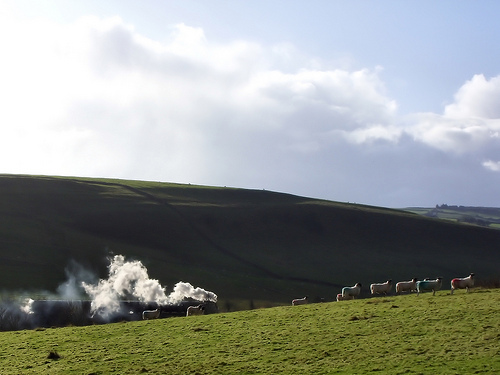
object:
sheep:
[394, 277, 417, 296]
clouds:
[405, 71, 496, 152]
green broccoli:
[408, 304, 414, 308]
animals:
[341, 281, 363, 299]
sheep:
[369, 279, 393, 295]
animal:
[415, 277, 443, 296]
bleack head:
[356, 281, 364, 288]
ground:
[296, 98, 382, 202]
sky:
[0, 1, 499, 179]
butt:
[451, 278, 460, 289]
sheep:
[448, 272, 478, 295]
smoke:
[70, 252, 222, 323]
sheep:
[450, 271, 473, 296]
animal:
[291, 296, 308, 306]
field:
[0, 285, 499, 375]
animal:
[140, 306, 161, 321]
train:
[2, 303, 214, 331]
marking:
[419, 281, 429, 288]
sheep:
[141, 307, 163, 322]